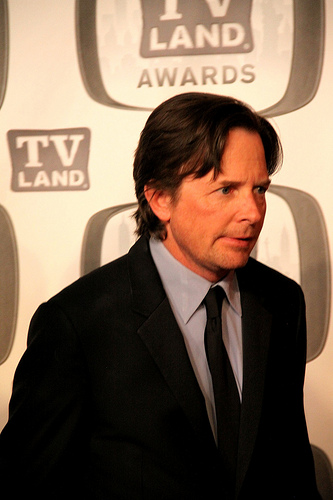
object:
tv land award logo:
[6, 123, 95, 194]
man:
[0, 88, 322, 500]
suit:
[4, 235, 315, 500]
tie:
[200, 279, 243, 465]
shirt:
[148, 233, 248, 459]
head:
[130, 91, 284, 273]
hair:
[129, 90, 284, 244]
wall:
[0, 0, 333, 500]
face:
[200, 137, 268, 270]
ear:
[142, 179, 170, 225]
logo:
[133, 0, 257, 91]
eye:
[207, 186, 237, 196]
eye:
[253, 186, 266, 195]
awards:
[136, 62, 260, 87]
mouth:
[223, 232, 255, 247]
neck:
[161, 223, 226, 286]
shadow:
[212, 279, 243, 337]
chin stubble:
[211, 247, 251, 272]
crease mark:
[37, 392, 83, 460]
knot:
[204, 284, 224, 320]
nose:
[234, 187, 261, 227]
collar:
[148, 236, 243, 323]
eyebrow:
[217, 176, 242, 191]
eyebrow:
[254, 176, 272, 189]